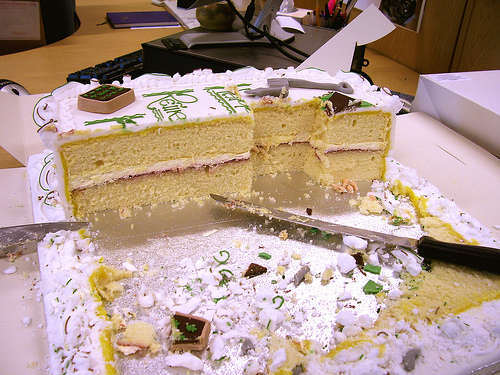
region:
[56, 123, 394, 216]
Layers of the cake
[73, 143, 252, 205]
The red jelly and frosting in the middle of the cake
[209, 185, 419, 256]
the blade covered in cake and frosting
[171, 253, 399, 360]
crumbs left all over the cake platter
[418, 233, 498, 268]
the black knife handle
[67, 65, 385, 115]
Gradening designs on the cake top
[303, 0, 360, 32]
pencils and pens sticking out of the holder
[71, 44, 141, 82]
Part of the black keyboard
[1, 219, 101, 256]
Another knife hanging off the cake tray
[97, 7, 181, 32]
A small purple notepad on the desk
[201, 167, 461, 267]
this is a knife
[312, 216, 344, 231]
this is the cutting edge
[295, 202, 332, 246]
the cutting edge is metallic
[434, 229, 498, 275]
this is the handle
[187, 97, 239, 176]
this is a cake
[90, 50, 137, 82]
this is the keyboard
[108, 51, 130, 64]
the buttons are black in color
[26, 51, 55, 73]
this is the table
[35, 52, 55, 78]
the table is brown in color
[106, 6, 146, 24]
this is a book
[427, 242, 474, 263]
the handle is black in color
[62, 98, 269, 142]
this is a cake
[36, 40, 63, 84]
this is a table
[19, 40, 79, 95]
the table is brown in color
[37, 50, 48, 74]
the table is wooden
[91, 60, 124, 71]
this is a keyboard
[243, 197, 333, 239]
this is the cutting edge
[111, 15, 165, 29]
this is a book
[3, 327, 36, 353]
portion of white cardboard box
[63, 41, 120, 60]
light brown surface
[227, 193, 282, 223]
cake on the knife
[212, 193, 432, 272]
silver blade on the knife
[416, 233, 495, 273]
black handle on the knife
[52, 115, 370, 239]
cut cake on the table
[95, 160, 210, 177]
white frosting in the cake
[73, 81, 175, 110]
green color on top of cake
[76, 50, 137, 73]
black remote on table top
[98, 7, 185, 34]
purple book on table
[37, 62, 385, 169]
a white leftover cake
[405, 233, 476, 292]
knife's handle is black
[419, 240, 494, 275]
knife's handle is black